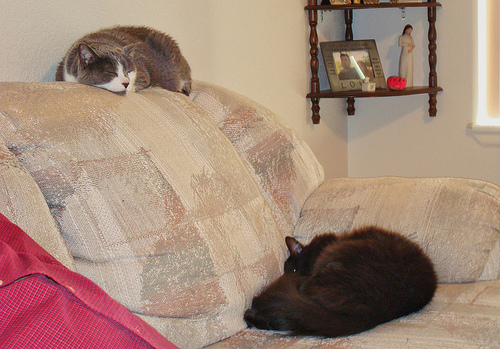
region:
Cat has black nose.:
[118, 82, 133, 88]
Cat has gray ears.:
[71, 33, 163, 68]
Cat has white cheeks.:
[103, 70, 168, 110]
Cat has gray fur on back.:
[115, 30, 175, 55]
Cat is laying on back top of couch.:
[59, 20, 227, 118]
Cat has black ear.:
[282, 228, 306, 265]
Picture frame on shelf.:
[318, 33, 389, 100]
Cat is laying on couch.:
[264, 208, 366, 335]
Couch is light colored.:
[35, 117, 425, 313]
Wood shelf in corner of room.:
[288, 27, 465, 141]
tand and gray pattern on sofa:
[127, 139, 305, 207]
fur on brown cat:
[361, 225, 406, 264]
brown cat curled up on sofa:
[241, 217, 448, 311]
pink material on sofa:
[27, 258, 118, 322]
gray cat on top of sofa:
[64, 11, 204, 114]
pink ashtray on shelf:
[379, 69, 426, 99]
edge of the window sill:
[455, 88, 497, 133]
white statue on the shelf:
[395, 22, 421, 81]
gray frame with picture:
[315, 29, 401, 96]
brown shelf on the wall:
[300, 1, 458, 128]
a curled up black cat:
[243, 226, 438, 338]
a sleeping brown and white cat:
[56, 24, 195, 95]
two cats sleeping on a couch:
[2, 25, 499, 347]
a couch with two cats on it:
[2, 23, 498, 347]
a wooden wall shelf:
[303, 0, 443, 126]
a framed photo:
[320, 39, 387, 92]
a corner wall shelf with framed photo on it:
[305, 1, 442, 126]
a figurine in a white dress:
[397, 23, 416, 86]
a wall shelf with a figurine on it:
[302, 0, 447, 127]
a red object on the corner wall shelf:
[385, 74, 408, 91]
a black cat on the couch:
[241, 220, 441, 336]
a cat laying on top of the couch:
[52, 25, 194, 97]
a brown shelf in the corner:
[301, 2, 444, 124]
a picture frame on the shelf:
[316, 33, 388, 99]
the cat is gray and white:
[53, 23, 192, 96]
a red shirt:
[0, 213, 184, 347]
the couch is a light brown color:
[0, 77, 496, 347]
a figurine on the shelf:
[396, 22, 417, 87]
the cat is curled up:
[246, 219, 437, 336]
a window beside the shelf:
[468, 0, 498, 140]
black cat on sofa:
[258, 231, 329, 327]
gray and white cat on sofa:
[67, 59, 186, 88]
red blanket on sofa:
[6, 260, 72, 316]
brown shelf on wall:
[291, 82, 328, 112]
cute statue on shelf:
[395, 22, 413, 77]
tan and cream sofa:
[124, 213, 204, 266]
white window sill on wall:
[471, 121, 490, 153]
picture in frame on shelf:
[323, 43, 376, 89]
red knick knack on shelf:
[393, 83, 407, 92]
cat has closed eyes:
[101, 58, 142, 117]